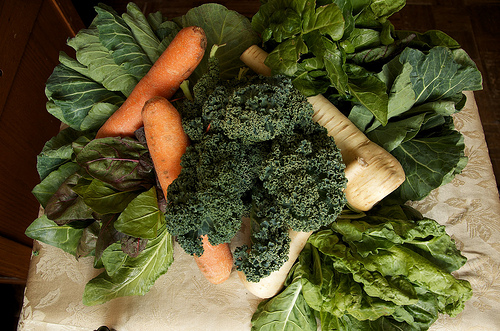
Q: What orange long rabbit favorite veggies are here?
A: Carrots.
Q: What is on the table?
A: Green food.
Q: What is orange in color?
A: The carrot.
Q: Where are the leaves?
A: On the table.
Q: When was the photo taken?
A: During the daytime.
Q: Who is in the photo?
A: No people.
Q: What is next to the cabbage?
A: Carrots.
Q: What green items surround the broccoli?
A: Lettuce.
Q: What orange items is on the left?
A: Carrots.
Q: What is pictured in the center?
A: Broccoli.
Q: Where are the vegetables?
A: On a table.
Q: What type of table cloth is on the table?
A: Tan.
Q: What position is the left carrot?
A: Diagonal.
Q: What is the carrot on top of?
A: Lettuce leaves.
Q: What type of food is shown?
A: Vegetables.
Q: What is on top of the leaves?
A: Two unpeeled carrots.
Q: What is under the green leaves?
A: Two white radish.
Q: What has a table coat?
A: The small table.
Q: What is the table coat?
A: Tan.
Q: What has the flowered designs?
A: The tablecloth.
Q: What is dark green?
A: Leaves.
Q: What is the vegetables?
A: Long and white.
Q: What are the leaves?
A: Green and red.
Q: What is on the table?
A: The orange carrot.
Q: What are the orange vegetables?
A: Carrots.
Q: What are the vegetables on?
A: A table.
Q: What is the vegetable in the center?
A: Broccoli.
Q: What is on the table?
A: Vegetables.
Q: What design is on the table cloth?
A: Leaves.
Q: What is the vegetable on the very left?
A: Lettuce.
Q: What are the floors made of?
A: Wood.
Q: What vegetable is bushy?
A: The broccoli.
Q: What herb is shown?
A: Oregano.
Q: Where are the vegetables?
A: On a pillow.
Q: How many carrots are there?
A: Two.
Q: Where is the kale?
A: In the center.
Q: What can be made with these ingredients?
A: A salad.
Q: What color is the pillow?
A: White.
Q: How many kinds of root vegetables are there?
A: Two.